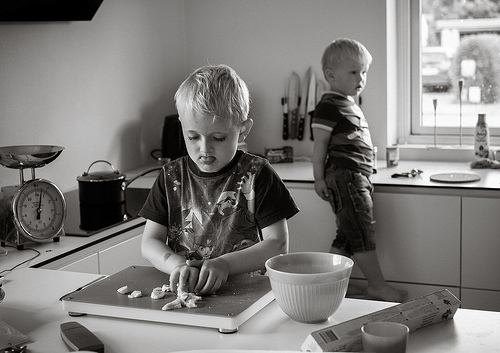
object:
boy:
[136, 63, 301, 295]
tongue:
[197, 157, 219, 164]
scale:
[0, 144, 69, 250]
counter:
[0, 265, 500, 351]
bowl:
[264, 251, 355, 324]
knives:
[303, 72, 318, 142]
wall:
[182, 0, 393, 166]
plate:
[427, 171, 485, 183]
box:
[298, 286, 461, 351]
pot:
[76, 158, 163, 231]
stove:
[40, 185, 158, 239]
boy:
[310, 37, 406, 303]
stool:
[337, 289, 389, 302]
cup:
[359, 319, 409, 353]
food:
[160, 295, 183, 311]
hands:
[186, 255, 232, 296]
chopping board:
[59, 264, 274, 334]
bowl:
[0, 145, 66, 171]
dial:
[11, 176, 66, 242]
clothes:
[310, 90, 374, 176]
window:
[384, 0, 499, 152]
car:
[417, 46, 454, 93]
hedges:
[448, 31, 500, 108]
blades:
[306, 73, 318, 114]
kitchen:
[0, 0, 499, 353]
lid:
[76, 158, 126, 184]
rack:
[277, 94, 364, 108]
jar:
[383, 143, 399, 170]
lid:
[383, 144, 399, 150]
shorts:
[322, 161, 380, 256]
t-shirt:
[138, 149, 300, 276]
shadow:
[118, 117, 144, 173]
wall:
[0, 0, 188, 204]